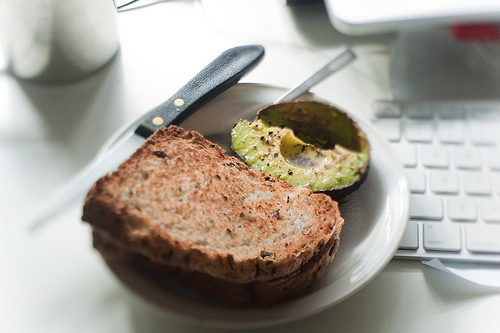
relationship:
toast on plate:
[95, 82, 411, 327] [90, 81, 410, 329]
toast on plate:
[93, 232, 341, 305] [90, 81, 410, 329]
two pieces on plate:
[75, 133, 316, 286] [105, 64, 407, 307]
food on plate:
[80, 99, 370, 309] [90, 81, 410, 329]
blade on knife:
[19, 124, 143, 236] [8, 40, 274, 245]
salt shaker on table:
[0, 0, 120, 79] [4, 83, 111, 150]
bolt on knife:
[170, 95, 194, 110] [25, 45, 256, 244]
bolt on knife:
[152, 116, 165, 126] [25, 45, 256, 244]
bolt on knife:
[150, 112, 165, 124] [8, 40, 274, 245]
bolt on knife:
[173, 97, 187, 107] [8, 40, 274, 245]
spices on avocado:
[258, 126, 278, 161] [231, 101, 371, 200]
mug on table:
[0, 1, 120, 85] [7, 2, 497, 329]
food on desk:
[80, 98, 372, 311] [1, 2, 498, 332]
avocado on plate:
[218, 98, 371, 194] [90, 81, 410, 329]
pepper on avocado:
[250, 123, 277, 160] [231, 91, 409, 217]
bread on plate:
[77, 124, 343, 305] [90, 81, 410, 329]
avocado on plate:
[231, 101, 371, 200] [80, 67, 450, 329]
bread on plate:
[77, 124, 343, 305] [80, 67, 450, 329]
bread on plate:
[123, 136, 340, 270] [90, 81, 410, 329]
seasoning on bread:
[153, 150, 217, 230] [84, 120, 344, 280]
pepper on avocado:
[250, 123, 277, 160] [228, 95, 377, 197]